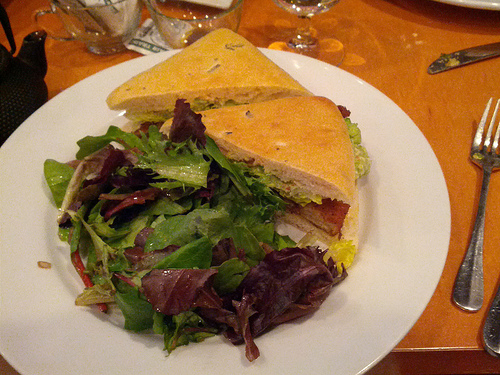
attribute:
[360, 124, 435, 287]
plate — rounded, white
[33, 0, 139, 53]
cup — clear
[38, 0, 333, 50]
glasses — table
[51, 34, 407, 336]
plate — white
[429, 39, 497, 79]
knife — silver, shiny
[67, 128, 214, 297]
lettuce — purple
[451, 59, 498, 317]
silverware — pair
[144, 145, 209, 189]
lettuce — purple, green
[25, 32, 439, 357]
food — on plate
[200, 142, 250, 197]
lettuce — green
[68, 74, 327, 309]
food — on plate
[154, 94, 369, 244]
sandwich — on table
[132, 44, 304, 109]
sandwich — on plate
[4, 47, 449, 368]
plate — white, on table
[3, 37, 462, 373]
white plate — on table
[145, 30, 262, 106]
bread — yellow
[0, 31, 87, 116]
spout — dark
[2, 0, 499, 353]
table — under plate